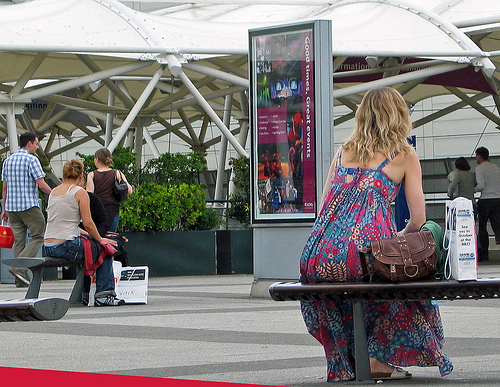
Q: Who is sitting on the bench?
A: A woman in a dress.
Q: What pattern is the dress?
A: Floral.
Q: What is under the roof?
A: Metal supports.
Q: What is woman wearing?
A: Dress.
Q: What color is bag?
A: White.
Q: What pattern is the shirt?
A: Plaid.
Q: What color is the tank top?
A: Brown.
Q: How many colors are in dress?
A: Three.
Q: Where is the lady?
A: On bench.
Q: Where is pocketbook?
A: Bench.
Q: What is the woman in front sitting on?
A: Bench.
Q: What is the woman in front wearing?
A: Dress.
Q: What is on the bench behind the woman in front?
A: Purse.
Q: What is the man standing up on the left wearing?
A: Plaid shirt.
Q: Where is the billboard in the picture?
A: Behind the woman.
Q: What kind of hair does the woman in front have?
A: Short and wavy.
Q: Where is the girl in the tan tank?
A: On the bench.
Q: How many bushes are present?
A: 4.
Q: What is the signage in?
A: Metal billboard.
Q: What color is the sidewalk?
A: Gray.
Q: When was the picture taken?
A: Daytime.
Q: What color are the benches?
A: Black and gray.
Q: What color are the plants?
A: Green.